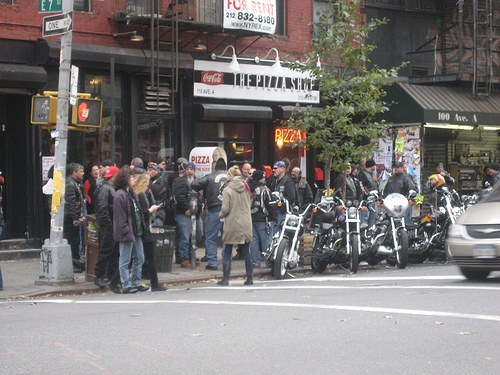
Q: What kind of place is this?
A: It is a road.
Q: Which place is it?
A: It is a road.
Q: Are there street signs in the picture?
A: Yes, there is a street sign.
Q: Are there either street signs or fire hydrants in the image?
A: Yes, there is a street sign.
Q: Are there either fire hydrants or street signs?
A: Yes, there is a street sign.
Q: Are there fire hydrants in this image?
A: No, there are no fire hydrants.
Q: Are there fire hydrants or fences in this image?
A: No, there are no fire hydrants or fences.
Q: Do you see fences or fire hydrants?
A: No, there are no fire hydrants or fences.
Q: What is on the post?
A: The street sign is on the post.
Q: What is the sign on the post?
A: The sign is a street sign.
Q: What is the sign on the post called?
A: The sign is a street sign.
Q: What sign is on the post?
A: The sign is a street sign.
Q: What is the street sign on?
A: The street sign is on the post.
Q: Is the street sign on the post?
A: Yes, the street sign is on the post.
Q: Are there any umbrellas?
A: No, there are no umbrellas.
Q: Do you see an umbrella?
A: No, there are no umbrellas.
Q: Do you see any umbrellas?
A: No, there are no umbrellas.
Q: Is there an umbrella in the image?
A: No, there are no umbrellas.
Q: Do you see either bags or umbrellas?
A: No, there are no umbrellas or bags.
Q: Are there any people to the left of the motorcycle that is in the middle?
A: Yes, there are people to the left of the motorcycle.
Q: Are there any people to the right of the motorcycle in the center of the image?
A: No, the people are to the left of the motorbike.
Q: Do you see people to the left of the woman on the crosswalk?
A: Yes, there are people to the left of the woman.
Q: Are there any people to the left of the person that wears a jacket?
A: Yes, there are people to the left of the woman.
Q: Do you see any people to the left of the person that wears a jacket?
A: Yes, there are people to the left of the woman.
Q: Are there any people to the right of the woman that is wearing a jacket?
A: No, the people are to the left of the woman.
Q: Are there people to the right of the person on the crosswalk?
A: No, the people are to the left of the woman.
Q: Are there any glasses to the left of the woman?
A: No, there are people to the left of the woman.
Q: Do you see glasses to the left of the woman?
A: No, there are people to the left of the woman.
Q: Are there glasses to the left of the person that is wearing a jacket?
A: No, there are people to the left of the woman.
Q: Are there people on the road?
A: Yes, there are people on the road.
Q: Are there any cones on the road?
A: No, there are people on the road.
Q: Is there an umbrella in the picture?
A: No, there are no umbrellas.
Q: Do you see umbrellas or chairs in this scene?
A: No, there are no umbrellas or chairs.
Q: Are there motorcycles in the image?
A: Yes, there is a motorcycle.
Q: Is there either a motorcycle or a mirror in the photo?
A: Yes, there is a motorcycle.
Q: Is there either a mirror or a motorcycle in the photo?
A: Yes, there is a motorcycle.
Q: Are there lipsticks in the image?
A: No, there are no lipsticks.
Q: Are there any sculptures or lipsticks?
A: No, there are no lipsticks or sculptures.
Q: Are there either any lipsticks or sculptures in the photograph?
A: No, there are no lipsticks or sculptures.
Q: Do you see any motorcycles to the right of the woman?
A: Yes, there is a motorcycle to the right of the woman.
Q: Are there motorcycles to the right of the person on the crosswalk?
A: Yes, there is a motorcycle to the right of the woman.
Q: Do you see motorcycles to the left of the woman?
A: No, the motorcycle is to the right of the woman.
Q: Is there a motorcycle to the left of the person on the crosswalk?
A: No, the motorcycle is to the right of the woman.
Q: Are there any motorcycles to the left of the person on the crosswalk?
A: No, the motorcycle is to the right of the woman.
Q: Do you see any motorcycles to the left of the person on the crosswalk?
A: No, the motorcycle is to the right of the woman.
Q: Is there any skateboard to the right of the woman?
A: No, there is a motorcycle to the right of the woman.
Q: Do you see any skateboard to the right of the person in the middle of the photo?
A: No, there is a motorcycle to the right of the woman.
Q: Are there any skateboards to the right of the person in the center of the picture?
A: No, there is a motorcycle to the right of the woman.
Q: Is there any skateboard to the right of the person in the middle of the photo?
A: No, there is a motorcycle to the right of the woman.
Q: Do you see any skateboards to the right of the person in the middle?
A: No, there is a motorcycle to the right of the woman.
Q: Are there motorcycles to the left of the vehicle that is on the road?
A: Yes, there is a motorcycle to the left of the car.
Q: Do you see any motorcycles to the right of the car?
A: No, the motorcycle is to the left of the car.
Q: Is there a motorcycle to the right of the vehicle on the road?
A: No, the motorcycle is to the left of the car.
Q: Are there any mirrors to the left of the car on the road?
A: No, there is a motorcycle to the left of the car.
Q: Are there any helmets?
A: Yes, there is a helmet.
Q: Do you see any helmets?
A: Yes, there is a helmet.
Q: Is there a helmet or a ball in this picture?
A: Yes, there is a helmet.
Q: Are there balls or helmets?
A: Yes, there is a helmet.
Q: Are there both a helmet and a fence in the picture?
A: No, there is a helmet but no fences.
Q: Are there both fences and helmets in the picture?
A: No, there is a helmet but no fences.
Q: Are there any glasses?
A: No, there are no glasses.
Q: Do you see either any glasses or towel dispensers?
A: No, there are no glasses or towel dispensers.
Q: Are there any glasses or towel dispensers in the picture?
A: No, there are no glasses or towel dispensers.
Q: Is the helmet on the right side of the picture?
A: Yes, the helmet is on the right of the image.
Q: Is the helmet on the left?
A: No, the helmet is on the right of the image.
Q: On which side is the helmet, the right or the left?
A: The helmet is on the right of the image.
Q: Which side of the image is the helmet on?
A: The helmet is on the right of the image.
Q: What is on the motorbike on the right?
A: The helmet is on the motorbike.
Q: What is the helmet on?
A: The helmet is on the motorcycle.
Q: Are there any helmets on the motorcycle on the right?
A: Yes, there is a helmet on the motorbike.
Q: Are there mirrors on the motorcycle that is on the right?
A: No, there is a helmet on the motorbike.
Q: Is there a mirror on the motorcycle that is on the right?
A: No, there is a helmet on the motorbike.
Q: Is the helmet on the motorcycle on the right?
A: Yes, the helmet is on the motorbike.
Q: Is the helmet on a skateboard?
A: No, the helmet is on the motorbike.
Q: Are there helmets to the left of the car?
A: Yes, there is a helmet to the left of the car.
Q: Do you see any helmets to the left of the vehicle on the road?
A: Yes, there is a helmet to the left of the car.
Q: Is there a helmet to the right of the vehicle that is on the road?
A: No, the helmet is to the left of the car.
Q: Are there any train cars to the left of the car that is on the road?
A: No, there is a helmet to the left of the car.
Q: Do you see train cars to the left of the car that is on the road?
A: No, there is a helmet to the left of the car.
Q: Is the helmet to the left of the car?
A: Yes, the helmet is to the left of the car.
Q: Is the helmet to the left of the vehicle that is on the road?
A: Yes, the helmet is to the left of the car.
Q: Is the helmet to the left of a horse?
A: No, the helmet is to the left of the car.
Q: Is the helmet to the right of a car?
A: No, the helmet is to the left of a car.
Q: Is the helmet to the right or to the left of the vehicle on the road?
A: The helmet is to the left of the car.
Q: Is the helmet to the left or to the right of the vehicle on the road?
A: The helmet is to the left of the car.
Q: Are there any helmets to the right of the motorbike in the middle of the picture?
A: Yes, there is a helmet to the right of the motorcycle.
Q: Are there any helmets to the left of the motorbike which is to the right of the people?
A: No, the helmet is to the right of the motorcycle.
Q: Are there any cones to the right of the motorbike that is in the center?
A: No, there is a helmet to the right of the motorbike.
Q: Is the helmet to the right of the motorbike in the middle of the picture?
A: Yes, the helmet is to the right of the motorcycle.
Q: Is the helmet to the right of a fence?
A: No, the helmet is to the right of the motorcycle.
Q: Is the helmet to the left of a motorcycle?
A: No, the helmet is to the right of a motorcycle.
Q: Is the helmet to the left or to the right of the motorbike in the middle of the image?
A: The helmet is to the right of the motorcycle.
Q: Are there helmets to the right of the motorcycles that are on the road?
A: Yes, there is a helmet to the right of the motorcycles.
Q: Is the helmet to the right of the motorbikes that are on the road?
A: Yes, the helmet is to the right of the motorcycles.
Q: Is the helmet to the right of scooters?
A: No, the helmet is to the right of the motorcycles.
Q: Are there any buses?
A: No, there are no buses.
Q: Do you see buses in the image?
A: No, there are no buses.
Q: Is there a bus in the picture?
A: No, there are no buses.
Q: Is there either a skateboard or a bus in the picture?
A: No, there are no buses or skateboards.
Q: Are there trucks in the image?
A: No, there are no trucks.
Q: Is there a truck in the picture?
A: No, there are no trucks.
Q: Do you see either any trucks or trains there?
A: No, there are no trucks or trains.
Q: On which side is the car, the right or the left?
A: The car is on the right of the image.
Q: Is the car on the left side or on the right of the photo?
A: The car is on the right of the image.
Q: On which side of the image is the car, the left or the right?
A: The car is on the right of the image.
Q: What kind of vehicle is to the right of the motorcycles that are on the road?
A: The vehicle is a car.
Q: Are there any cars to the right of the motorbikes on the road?
A: Yes, there is a car to the right of the motorbikes.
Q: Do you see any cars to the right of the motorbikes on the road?
A: Yes, there is a car to the right of the motorbikes.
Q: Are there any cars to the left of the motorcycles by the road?
A: No, the car is to the right of the motorbikes.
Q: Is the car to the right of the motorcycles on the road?
A: Yes, the car is to the right of the motorcycles.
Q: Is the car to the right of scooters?
A: No, the car is to the right of the motorcycles.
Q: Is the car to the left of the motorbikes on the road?
A: No, the car is to the right of the motorcycles.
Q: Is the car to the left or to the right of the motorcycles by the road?
A: The car is to the right of the motorcycles.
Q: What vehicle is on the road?
A: The vehicle is a car.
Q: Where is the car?
A: The car is on the road.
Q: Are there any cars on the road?
A: Yes, there is a car on the road.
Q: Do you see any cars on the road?
A: Yes, there is a car on the road.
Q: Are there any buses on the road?
A: No, there is a car on the road.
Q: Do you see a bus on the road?
A: No, there is a car on the road.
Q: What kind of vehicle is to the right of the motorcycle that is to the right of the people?
A: The vehicle is a car.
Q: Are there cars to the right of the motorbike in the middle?
A: Yes, there is a car to the right of the motorcycle.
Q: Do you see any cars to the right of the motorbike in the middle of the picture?
A: Yes, there is a car to the right of the motorcycle.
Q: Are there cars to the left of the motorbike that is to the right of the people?
A: No, the car is to the right of the motorcycle.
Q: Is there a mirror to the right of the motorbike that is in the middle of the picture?
A: No, there is a car to the right of the motorcycle.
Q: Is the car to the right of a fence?
A: No, the car is to the right of a motorcycle.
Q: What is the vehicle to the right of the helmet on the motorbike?
A: The vehicle is a car.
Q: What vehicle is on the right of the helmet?
A: The vehicle is a car.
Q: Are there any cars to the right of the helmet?
A: Yes, there is a car to the right of the helmet.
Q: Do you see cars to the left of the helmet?
A: No, the car is to the right of the helmet.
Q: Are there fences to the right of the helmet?
A: No, there is a car to the right of the helmet.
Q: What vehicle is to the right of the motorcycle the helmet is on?
A: The vehicle is a car.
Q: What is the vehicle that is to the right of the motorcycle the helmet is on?
A: The vehicle is a car.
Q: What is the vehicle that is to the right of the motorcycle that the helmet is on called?
A: The vehicle is a car.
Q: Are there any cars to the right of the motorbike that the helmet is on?
A: Yes, there is a car to the right of the motorcycle.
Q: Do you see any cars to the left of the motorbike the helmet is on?
A: No, the car is to the right of the motorcycle.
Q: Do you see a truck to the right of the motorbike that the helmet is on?
A: No, there is a car to the right of the motorbike.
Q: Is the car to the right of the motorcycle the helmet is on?
A: Yes, the car is to the right of the motorbike.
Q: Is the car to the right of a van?
A: No, the car is to the right of the motorbike.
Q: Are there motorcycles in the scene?
A: Yes, there are motorcycles.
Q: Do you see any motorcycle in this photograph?
A: Yes, there are motorcycles.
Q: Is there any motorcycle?
A: Yes, there are motorcycles.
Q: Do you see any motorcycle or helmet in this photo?
A: Yes, there are motorcycles.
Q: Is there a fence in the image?
A: No, there are no fences.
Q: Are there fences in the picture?
A: No, there are no fences.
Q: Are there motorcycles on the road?
A: Yes, there are motorcycles on the road.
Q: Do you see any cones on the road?
A: No, there are motorcycles on the road.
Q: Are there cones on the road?
A: No, there are motorcycles on the road.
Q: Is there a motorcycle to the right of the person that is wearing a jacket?
A: Yes, there are motorcycles to the right of the woman.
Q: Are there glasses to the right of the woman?
A: No, there are motorcycles to the right of the woman.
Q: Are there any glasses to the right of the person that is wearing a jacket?
A: No, there are motorcycles to the right of the woman.